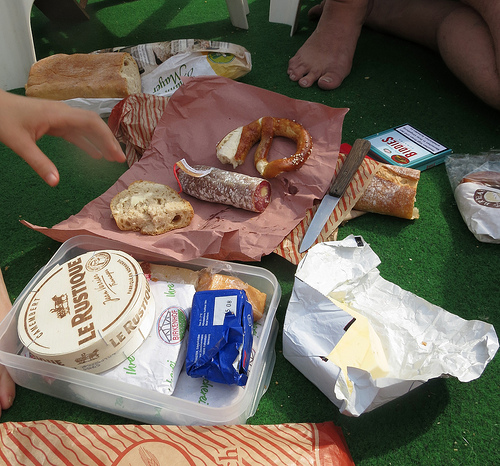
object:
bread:
[352, 163, 422, 221]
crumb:
[364, 76, 370, 80]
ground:
[0, 0, 500, 466]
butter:
[325, 290, 388, 394]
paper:
[282, 233, 500, 418]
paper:
[19, 76, 348, 262]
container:
[16, 249, 155, 376]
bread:
[216, 115, 314, 179]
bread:
[109, 179, 195, 235]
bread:
[24, 52, 142, 101]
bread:
[194, 268, 267, 322]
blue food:
[186, 288, 254, 387]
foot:
[287, 0, 371, 90]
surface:
[0, 0, 498, 465]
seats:
[226, 0, 302, 37]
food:
[108, 115, 314, 236]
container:
[0, 234, 282, 426]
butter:
[131, 192, 154, 205]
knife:
[299, 138, 371, 253]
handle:
[328, 139, 372, 199]